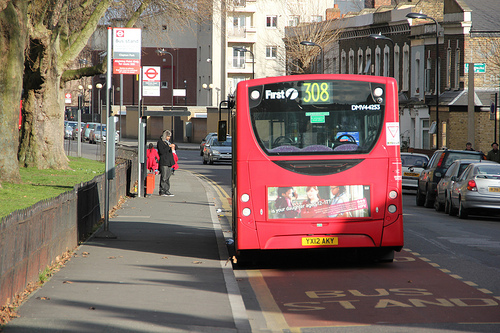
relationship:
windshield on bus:
[252, 110, 381, 151] [227, 80, 399, 256]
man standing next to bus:
[153, 128, 178, 194] [227, 80, 399, 256]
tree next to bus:
[2, 1, 85, 177] [227, 80, 399, 256]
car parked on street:
[425, 150, 493, 189] [180, 149, 499, 323]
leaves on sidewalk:
[45, 257, 83, 264] [89, 156, 249, 328]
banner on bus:
[265, 187, 376, 216] [227, 80, 399, 256]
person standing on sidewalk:
[153, 128, 178, 194] [89, 156, 249, 328]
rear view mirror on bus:
[218, 120, 229, 143] [227, 80, 399, 256]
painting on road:
[291, 285, 486, 307] [180, 149, 499, 323]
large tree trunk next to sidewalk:
[26, 34, 76, 173] [89, 156, 249, 328]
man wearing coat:
[156, 128, 179, 194] [157, 137, 173, 163]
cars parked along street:
[388, 150, 496, 206] [180, 149, 499, 323]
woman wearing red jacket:
[145, 145, 162, 177] [145, 149, 156, 164]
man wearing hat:
[153, 128, 178, 194] [159, 130, 175, 138]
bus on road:
[227, 80, 399, 256] [180, 149, 499, 323]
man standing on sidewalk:
[156, 128, 179, 194] [89, 156, 249, 328]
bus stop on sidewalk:
[129, 60, 165, 196] [89, 156, 249, 328]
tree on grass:
[2, 1, 85, 177] [9, 164, 124, 202]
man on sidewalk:
[156, 128, 179, 194] [89, 156, 249, 328]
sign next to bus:
[140, 66, 162, 96] [227, 80, 399, 256]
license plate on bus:
[301, 233, 338, 246] [227, 80, 399, 256]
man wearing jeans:
[153, 128, 178, 194] [159, 165, 167, 193]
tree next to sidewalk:
[2, 1, 85, 177] [89, 156, 249, 328]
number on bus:
[302, 82, 330, 104] [227, 80, 399, 256]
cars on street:
[388, 150, 496, 206] [180, 149, 499, 323]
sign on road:
[140, 66, 162, 96] [180, 149, 499, 323]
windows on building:
[233, 52, 243, 64] [196, 8, 301, 105]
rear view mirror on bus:
[214, 120, 227, 143] [227, 80, 399, 256]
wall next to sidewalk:
[2, 176, 171, 259] [89, 156, 249, 328]